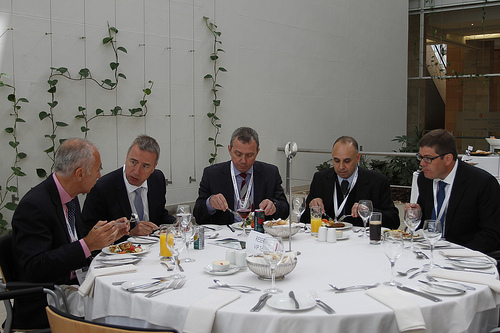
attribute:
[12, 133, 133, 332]
man — eating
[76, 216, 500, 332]
table — circular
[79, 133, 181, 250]
man — eating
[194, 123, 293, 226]
man — eating, sitting, black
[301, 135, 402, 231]
man — eating, talking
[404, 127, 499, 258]
man — eating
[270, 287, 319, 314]
plate — empty, white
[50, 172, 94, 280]
shirt — pink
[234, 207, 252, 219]
wine — red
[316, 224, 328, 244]
shaker — salt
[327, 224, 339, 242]
shaker — pepper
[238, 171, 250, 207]
tie — striped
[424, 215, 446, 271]
glass — empty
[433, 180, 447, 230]
tie — blue, dark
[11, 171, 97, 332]
suit — black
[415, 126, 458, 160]
hair — dark, brown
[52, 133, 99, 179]
hair — receding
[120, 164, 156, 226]
shirt — white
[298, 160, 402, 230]
jacket — black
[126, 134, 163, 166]
hair — gray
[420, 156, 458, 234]
shirt — white